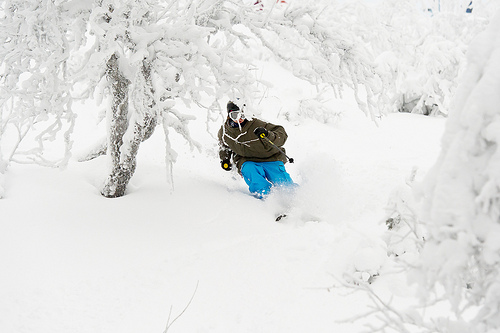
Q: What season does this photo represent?
A: Winter.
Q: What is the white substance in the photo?
A: Snow.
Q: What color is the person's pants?
A: Blue.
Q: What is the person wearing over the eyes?
A: Goggles.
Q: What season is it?
A: Winter.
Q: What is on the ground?
A: Snow.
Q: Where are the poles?
A: Skier's hands.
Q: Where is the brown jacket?
A: On skier.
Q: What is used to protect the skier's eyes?
A: Goggles.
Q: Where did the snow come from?
A: Clouds.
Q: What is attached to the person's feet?
A: Skis.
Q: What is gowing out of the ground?
A: Trees.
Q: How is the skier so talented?
A: Years of practice.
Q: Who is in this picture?
A: A skier.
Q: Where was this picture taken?
A: A mountain.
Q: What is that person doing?
A: Skiing.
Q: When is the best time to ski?
A: The winter.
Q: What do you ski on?
A: Snow and skis.